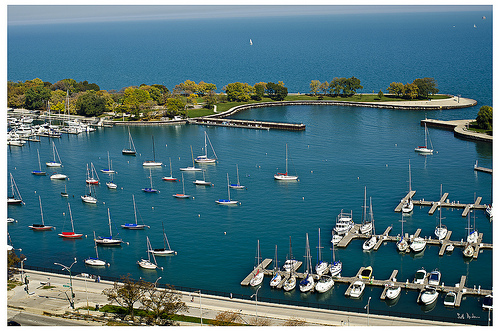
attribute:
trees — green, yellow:
[8, 76, 288, 117]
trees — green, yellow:
[309, 76, 362, 96]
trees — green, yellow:
[387, 77, 439, 97]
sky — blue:
[52, 30, 123, 73]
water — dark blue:
[37, 24, 239, 70]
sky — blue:
[80, 3, 202, 30]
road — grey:
[8, 264, 470, 325]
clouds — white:
[191, 13, 286, 58]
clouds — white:
[404, 43, 454, 70]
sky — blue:
[98, 17, 140, 28]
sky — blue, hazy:
[7, 7, 167, 19]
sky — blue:
[3, 6, 490, 25]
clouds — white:
[8, 5, 488, 25]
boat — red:
[321, 213, 358, 236]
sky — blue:
[17, 0, 413, 18]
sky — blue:
[1, 9, 496, 19]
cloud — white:
[8, 7, 485, 25]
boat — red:
[56, 199, 86, 240]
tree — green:
[267, 81, 288, 101]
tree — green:
[309, 75, 321, 95]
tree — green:
[180, 77, 199, 98]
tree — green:
[383, 78, 405, 97]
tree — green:
[413, 75, 439, 100]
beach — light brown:
[366, 94, 476, 110]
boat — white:
[346, 277, 366, 299]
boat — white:
[356, 261, 375, 282]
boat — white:
[406, 232, 426, 253]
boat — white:
[444, 242, 454, 252]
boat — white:
[399, 156, 416, 212]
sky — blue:
[9, 7, 489, 30]